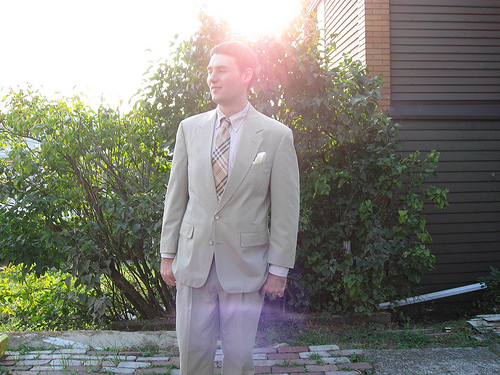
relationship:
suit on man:
[157, 101, 301, 365] [157, 42, 307, 371]